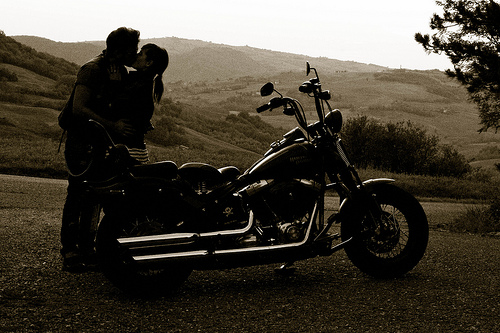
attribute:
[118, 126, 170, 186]
skirt — striped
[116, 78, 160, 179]
shirt — white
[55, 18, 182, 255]
couple — kissing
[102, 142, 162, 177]
woman wearing skirt — black, white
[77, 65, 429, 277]
motorcycle — black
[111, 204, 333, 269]
exhaust — long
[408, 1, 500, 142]
tree — leafy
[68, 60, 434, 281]
bike — metal, black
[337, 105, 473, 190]
bush — lush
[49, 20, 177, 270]
man and woman — side-view, kissing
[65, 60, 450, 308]
motorcycle — black, chrome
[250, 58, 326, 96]
mirrors on — top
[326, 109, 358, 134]
front headlight — one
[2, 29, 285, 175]
rolling hills — behind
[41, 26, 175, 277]
couple kissing — shadowed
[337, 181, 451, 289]
front wheel — one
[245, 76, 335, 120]
two handlebars — motorcycle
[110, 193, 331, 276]
two exhaust pipes — shiny, chrome, motorcyle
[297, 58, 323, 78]
front mirror — one, motorcycle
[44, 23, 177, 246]
two people — embracing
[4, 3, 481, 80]
sky is grey — overcast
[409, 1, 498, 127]
thin tree — behind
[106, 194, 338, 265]
exhaust pipes — reflective